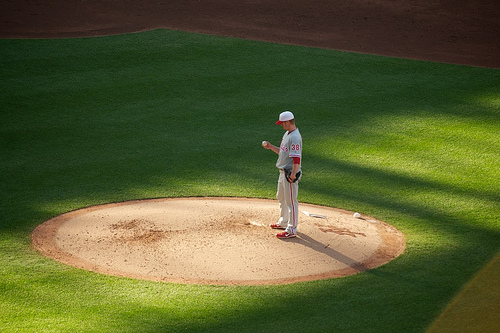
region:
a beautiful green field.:
[71, 45, 290, 105]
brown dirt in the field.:
[340, 1, 420, 37]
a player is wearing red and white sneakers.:
[270, 225, 310, 240]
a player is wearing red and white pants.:
[281, 185, 301, 217]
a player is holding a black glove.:
[280, 165, 300, 180]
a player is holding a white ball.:
[250, 130, 276, 156]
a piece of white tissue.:
[340, 196, 377, 226]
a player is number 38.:
[282, 135, 307, 155]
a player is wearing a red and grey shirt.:
[278, 133, 304, 163]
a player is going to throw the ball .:
[247, 91, 325, 258]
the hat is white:
[272, 108, 296, 125]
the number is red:
[289, 141, 303, 151]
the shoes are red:
[264, 216, 301, 243]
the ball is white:
[259, 136, 270, 149]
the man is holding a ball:
[250, 103, 325, 246]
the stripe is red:
[289, 189, 302, 230]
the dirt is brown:
[98, 213, 182, 271]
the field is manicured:
[75, 67, 183, 164]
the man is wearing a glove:
[281, 167, 305, 186]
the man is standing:
[242, 106, 318, 274]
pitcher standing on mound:
[252, 108, 307, 238]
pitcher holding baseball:
[256, 109, 317, 231]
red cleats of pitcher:
[272, 218, 290, 243]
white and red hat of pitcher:
[276, 113, 296, 129]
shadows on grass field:
[14, 28, 487, 277]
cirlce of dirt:
[36, 190, 394, 294]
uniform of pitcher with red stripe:
[265, 131, 312, 214]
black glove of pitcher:
[281, 163, 303, 180]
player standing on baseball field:
[251, 105, 310, 241]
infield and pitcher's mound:
[6, 20, 494, 331]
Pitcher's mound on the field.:
[31, 190, 409, 286]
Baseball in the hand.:
[257, 134, 269, 149]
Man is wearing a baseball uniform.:
[265, 108, 306, 243]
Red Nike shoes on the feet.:
[270, 220, 294, 240]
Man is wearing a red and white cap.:
[272, 107, 301, 134]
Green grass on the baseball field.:
[10, 30, 496, 202]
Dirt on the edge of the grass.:
[1, 2, 498, 69]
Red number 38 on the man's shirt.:
[289, 140, 299, 155]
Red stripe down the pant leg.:
[282, 172, 297, 237]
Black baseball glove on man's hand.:
[280, 167, 304, 185]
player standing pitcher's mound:
[252, 108, 312, 241]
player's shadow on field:
[276, 221, 413, 288]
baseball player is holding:
[262, 135, 272, 152]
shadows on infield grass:
[9, 37, 486, 332]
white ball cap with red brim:
[275, 108, 297, 127]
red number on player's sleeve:
[286, 143, 302, 160]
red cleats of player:
[265, 218, 298, 240]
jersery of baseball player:
[268, 131, 307, 168]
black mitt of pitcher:
[278, 168, 303, 185]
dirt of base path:
[12, 7, 487, 54]